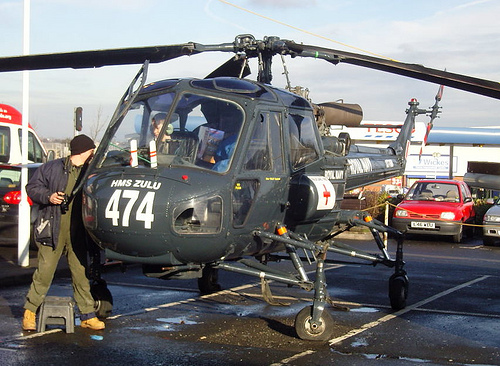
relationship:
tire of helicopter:
[276, 303, 341, 352] [47, 22, 467, 338]